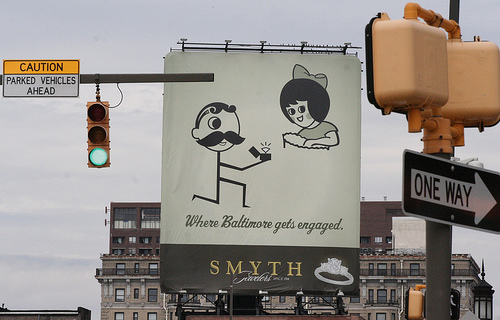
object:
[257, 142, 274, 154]
ring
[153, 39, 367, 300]
billboard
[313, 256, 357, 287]
ring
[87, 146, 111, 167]
light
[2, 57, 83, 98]
sign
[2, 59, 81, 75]
caution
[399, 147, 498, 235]
sign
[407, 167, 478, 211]
one way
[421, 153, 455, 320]
pole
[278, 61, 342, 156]
girl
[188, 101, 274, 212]
man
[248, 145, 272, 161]
box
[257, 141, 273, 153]
diamond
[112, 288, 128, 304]
windows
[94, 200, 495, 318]
building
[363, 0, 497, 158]
object